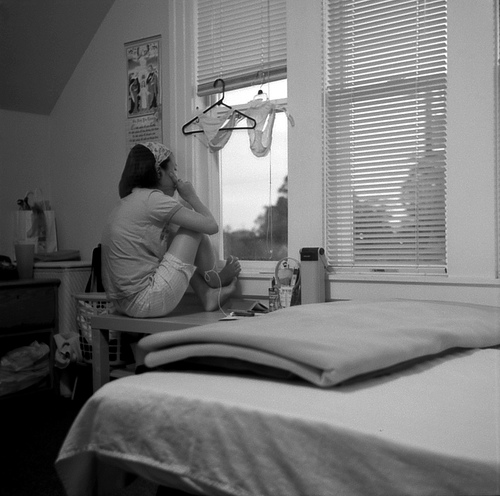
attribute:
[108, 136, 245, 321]
girl — backward, cross legged, dressed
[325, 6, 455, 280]
blinds — closed, thin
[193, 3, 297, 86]
blinds — open, partly open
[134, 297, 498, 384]
blanket — folded, light colored, stacked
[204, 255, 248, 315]
feet — bare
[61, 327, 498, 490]
bed — high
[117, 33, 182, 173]
poster — hanging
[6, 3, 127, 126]
roof — sloped